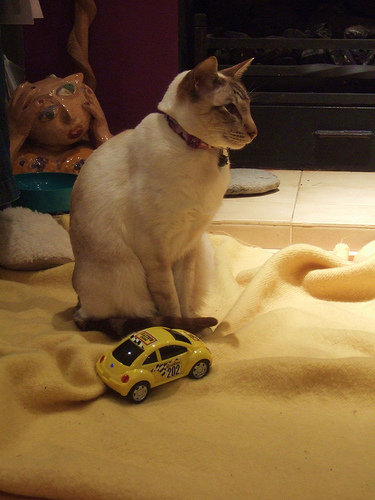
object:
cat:
[67, 54, 258, 343]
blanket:
[1, 229, 375, 497]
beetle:
[95, 323, 212, 407]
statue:
[8, 70, 114, 175]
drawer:
[230, 105, 375, 171]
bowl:
[11, 170, 78, 216]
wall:
[23, 1, 180, 139]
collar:
[156, 107, 229, 168]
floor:
[213, 171, 375, 231]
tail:
[75, 314, 218, 341]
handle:
[313, 130, 375, 141]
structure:
[177, 5, 375, 173]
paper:
[0, 0, 46, 26]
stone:
[224, 168, 281, 197]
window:
[158, 344, 188, 361]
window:
[142, 351, 159, 366]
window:
[165, 329, 192, 345]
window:
[112, 338, 145, 367]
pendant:
[217, 154, 228, 167]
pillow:
[0, 205, 75, 272]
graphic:
[150, 358, 181, 379]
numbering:
[166, 364, 180, 379]